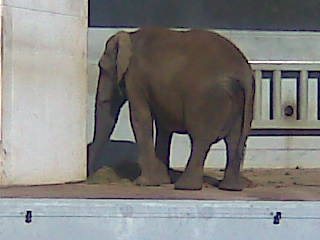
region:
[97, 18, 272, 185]
large and brown elephant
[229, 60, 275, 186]
elephant has brown tail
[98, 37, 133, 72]
elephant has folded ears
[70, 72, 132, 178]
elephant has brown trunk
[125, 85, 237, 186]
elephant has dark brown legs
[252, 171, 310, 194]
ground is brown and dry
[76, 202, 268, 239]
grey stone wall in front of elephant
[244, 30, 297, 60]
white wall behind elephant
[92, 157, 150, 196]
green grass under elephant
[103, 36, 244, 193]
large and brown elephant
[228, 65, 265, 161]
elephant has long tail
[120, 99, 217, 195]
elephant has brown legs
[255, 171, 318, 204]
ground is brown and dry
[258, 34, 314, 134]
grey wall behind elephant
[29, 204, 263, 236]
grey wall in front of elephant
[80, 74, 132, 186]
elephant has brown trunk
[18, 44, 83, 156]
white wall near elephant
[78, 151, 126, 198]
green grass near elephant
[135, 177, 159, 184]
Front elephant leg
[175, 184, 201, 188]
Rear elephant leg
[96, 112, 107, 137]
The trunk of the elephant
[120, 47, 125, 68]
The ear of the elephant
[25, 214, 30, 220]
A black mark on the side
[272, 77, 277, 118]
A vertical bar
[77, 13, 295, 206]
an elephant in a pen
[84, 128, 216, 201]
shadow cast by elephant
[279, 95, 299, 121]
a hole in the wall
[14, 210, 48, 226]
black piece that holds window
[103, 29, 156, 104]
an ear of the elephant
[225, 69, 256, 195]
long tail of elephant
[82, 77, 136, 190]
long trunk of elephant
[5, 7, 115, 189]
white stone wall by elephant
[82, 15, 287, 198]
one elephant standing alone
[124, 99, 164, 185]
this is a leg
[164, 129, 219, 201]
this is a leg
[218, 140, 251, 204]
this is a leg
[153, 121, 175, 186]
this is a leg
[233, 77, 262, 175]
this is a tail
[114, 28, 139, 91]
this is an ear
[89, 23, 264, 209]
this is an elephant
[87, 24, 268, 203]
this is a brown elephant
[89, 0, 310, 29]
this is a black surface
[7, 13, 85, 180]
this is a white surface